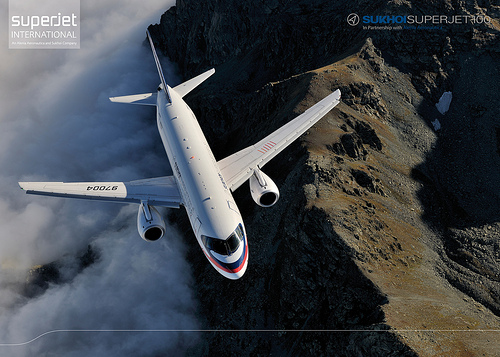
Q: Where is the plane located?
A: Over mountain.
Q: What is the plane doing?
A: Soaring in sky.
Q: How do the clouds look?
A: Fluffy.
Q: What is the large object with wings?
A: Plane.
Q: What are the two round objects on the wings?
A: Engines.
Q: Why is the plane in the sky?
A: Flying.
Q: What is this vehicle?
A: Airplane.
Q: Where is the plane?
A: Sky.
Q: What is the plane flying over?
A: Mountain.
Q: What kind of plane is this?
A: Passenger.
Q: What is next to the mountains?
A: Clouds.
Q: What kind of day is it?
A: Sunny.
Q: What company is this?
A: Superjet international.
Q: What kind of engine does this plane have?
A: Jet engines.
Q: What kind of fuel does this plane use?
A: Jet fuel.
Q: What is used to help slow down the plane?
A: Tires.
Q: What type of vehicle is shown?
A: Plane.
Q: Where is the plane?
A: Above mountains.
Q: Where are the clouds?
A: Covering left side of mountain.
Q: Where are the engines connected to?
A: Plane's wings.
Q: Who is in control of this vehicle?
A: Pilot.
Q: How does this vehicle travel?
A: By flying.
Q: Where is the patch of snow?
A: In a small valley.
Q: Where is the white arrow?
A: In white circle.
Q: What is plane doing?
A: Flying in sky.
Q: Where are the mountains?
A: Under plane.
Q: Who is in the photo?
A: Nobody.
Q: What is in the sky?
A: An airplane.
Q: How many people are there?
A: None.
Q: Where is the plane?
A: In the air.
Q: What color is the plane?
A: White.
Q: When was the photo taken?
A: Daytime.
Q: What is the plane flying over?
A: A mountain.